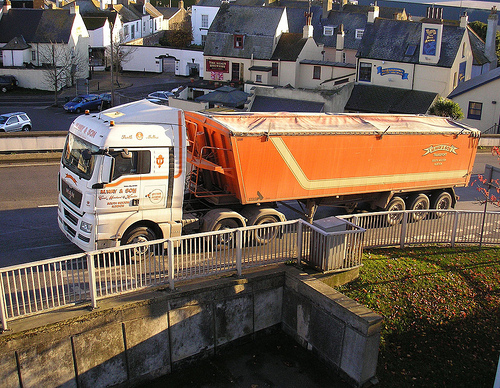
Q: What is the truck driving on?
A: A road bridge.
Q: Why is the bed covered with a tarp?
A: To prevent loose earth matter from flowing onto the streets.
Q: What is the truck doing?
A: Going up the ramp.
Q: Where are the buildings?
A: On the other side of the street.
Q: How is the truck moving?
A: On its six tires.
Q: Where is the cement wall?
A: Below the metal fence.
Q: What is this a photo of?
A: A truck.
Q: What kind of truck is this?
A: Diesel truck.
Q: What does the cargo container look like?
A: Orange.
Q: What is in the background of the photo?
A: The neighborhood.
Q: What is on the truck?
A: A white line.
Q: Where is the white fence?
A: Along the road.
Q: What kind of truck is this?
A: Industrial.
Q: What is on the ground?
A: Green grass.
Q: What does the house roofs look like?
A: Gray.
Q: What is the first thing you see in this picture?
A: Semi Truck.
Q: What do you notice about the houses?
A: Close together.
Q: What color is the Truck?
A: Orange.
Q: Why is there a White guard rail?
A: For Protection.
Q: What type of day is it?
A: Sunny.